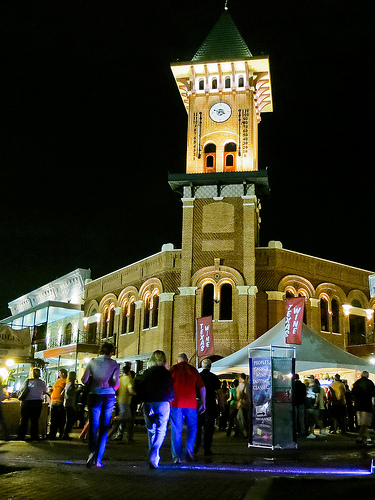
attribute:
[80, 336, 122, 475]
person — standing, going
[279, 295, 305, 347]
sign — red, white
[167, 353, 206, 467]
man — at festival, watching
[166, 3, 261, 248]
clock tower — illuminated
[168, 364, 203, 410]
shirt — red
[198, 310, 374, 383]
tent — white